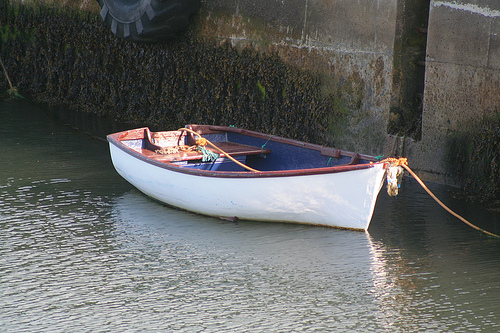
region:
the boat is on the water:
[102, 98, 389, 242]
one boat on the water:
[83, 79, 434, 299]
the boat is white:
[85, 84, 390, 283]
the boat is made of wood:
[103, 86, 464, 322]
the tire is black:
[99, 7, 208, 53]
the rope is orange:
[393, 155, 482, 260]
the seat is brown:
[132, 135, 319, 199]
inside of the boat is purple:
[260, 149, 332, 186]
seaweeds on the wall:
[222, 71, 356, 141]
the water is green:
[30, 140, 98, 187]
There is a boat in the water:
[65, 46, 460, 278]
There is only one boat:
[111, 28, 458, 330]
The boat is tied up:
[85, 61, 498, 296]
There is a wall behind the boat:
[43, 9, 496, 234]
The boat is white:
[74, 81, 406, 321]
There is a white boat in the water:
[98, 76, 418, 331]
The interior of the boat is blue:
[113, 94, 435, 294]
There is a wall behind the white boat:
[45, 1, 492, 300]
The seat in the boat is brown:
[118, 62, 388, 256]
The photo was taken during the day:
[4, 7, 456, 307]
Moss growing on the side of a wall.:
[9, 11, 327, 146]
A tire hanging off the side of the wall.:
[75, 0, 192, 60]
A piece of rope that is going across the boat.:
[0, 51, 497, 253]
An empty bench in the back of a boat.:
[140, 132, 259, 169]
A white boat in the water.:
[87, 117, 416, 245]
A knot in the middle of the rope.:
[360, 143, 426, 183]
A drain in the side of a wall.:
[369, 1, 449, 160]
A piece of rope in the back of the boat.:
[156, 137, 203, 161]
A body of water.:
[1, 108, 496, 332]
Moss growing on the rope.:
[5, 81, 26, 106]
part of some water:
[305, 266, 380, 312]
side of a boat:
[244, 197, 309, 219]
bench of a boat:
[222, 141, 242, 157]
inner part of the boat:
[271, 145, 288, 167]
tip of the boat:
[367, 160, 389, 182]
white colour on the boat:
[261, 188, 303, 208]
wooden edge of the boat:
[243, 168, 302, 179]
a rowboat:
[113, 116, 430, 236]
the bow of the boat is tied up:
[326, 140, 498, 274]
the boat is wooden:
[76, 127, 422, 186]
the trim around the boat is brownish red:
[103, 117, 405, 177]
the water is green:
[7, 245, 205, 317]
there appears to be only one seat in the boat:
[95, 121, 314, 171]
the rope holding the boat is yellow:
[161, 117, 493, 253]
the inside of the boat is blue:
[157, 111, 343, 175]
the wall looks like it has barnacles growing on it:
[8, 29, 317, 133]